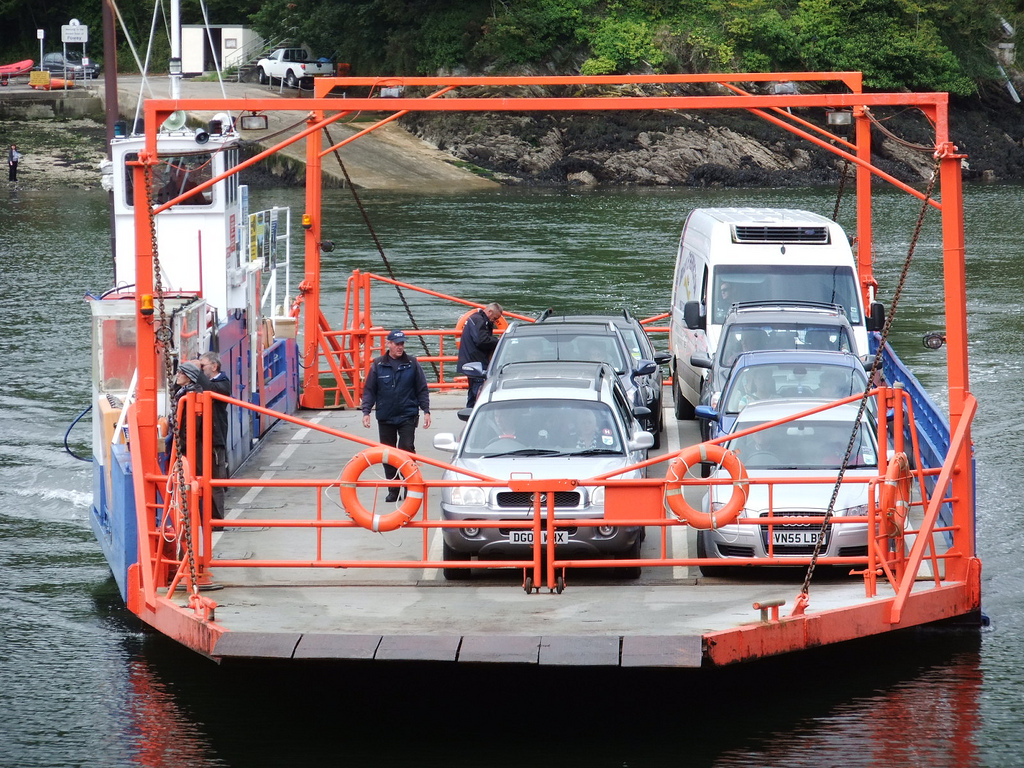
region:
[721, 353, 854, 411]
window on the building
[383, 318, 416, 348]
Man wearing a hat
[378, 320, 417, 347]
Man is wearing a hat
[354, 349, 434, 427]
Man wearing a jacket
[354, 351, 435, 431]
Man is wearing a jacket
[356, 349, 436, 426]
Man is wearing a navy blue jacket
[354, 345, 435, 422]
Man wearing a navy blue jacket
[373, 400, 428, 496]
Man wearing pants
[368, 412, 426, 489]
Man is wearing pants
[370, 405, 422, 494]
Man wearing black pants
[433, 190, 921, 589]
vehicles on the ferry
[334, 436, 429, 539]
orange safety donut on the ferry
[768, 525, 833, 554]
license plate on the car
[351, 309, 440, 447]
man in a uniform on the ferry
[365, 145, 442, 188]
road in back of the ferry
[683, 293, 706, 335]
mirror on the van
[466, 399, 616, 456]
people in the car on the ferry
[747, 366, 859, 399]
windshield on the car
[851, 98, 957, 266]
posts on the ferry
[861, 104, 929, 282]
ropes on the ferry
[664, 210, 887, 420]
Large white parked van.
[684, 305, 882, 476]
Grey suv in front of a white van.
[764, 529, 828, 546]
License plate that says VN55 LB5.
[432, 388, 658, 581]
Silver car with DCO on the license plate.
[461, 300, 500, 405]
Man in black coat leaning over by a car.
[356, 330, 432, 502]
Man in mostly black walking up to the front of the vehicles.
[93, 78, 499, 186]
Paved ramp going down into the water.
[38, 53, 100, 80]
Black car at the top of the ramp.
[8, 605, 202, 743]
the water is murky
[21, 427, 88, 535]
ripples in the water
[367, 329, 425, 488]
the man is in all black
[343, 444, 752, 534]
life preserves on the gate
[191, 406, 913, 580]
the gate rails are orange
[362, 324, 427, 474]
the man is standing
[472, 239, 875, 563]
cars on the raft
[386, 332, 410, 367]
man is in a hat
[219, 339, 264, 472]
the doors are blue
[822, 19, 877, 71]
green leaves on the tree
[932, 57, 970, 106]
green leaves on the tree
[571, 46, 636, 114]
green leaves on the tree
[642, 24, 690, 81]
green leaves on the tree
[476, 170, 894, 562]
Cars on a ferry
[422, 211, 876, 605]
Cars on a boat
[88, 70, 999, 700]
Ferry in the water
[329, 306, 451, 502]
Man in a black cap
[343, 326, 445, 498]
Man wearing black pants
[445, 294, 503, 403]
Man wearing black jacket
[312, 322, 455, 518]
Man looking at cars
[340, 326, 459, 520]
Man looking at car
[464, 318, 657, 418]
a car in a parking lot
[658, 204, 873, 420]
a car in a parking lot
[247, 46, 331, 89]
a car in a parking lot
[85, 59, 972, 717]
a boat on the water